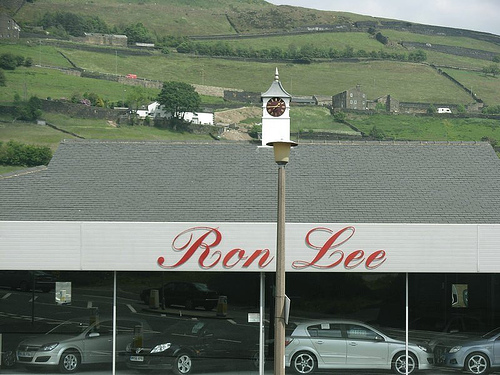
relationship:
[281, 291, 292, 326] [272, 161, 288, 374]
sign on a post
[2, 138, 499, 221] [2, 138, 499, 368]
roof of building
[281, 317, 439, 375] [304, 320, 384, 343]
car has window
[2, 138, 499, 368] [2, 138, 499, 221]
building has roof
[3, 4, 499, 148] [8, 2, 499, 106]
grass in hill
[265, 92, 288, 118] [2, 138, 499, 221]
clock on a roof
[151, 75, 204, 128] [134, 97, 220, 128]
tree on front a house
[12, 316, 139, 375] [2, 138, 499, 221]
car under roof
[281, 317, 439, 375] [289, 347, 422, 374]
car has wheel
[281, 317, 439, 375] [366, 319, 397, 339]
car has windshield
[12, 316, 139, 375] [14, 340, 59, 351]
car has headlight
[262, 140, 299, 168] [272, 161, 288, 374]
lamp on a post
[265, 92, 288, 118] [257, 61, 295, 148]
clock on a tower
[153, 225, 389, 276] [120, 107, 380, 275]
letters on wall